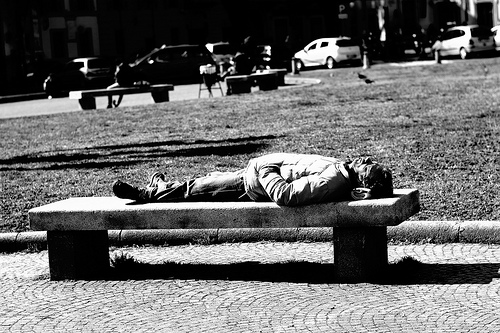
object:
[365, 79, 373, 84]
bird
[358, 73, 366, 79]
bird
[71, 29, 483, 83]
parking lot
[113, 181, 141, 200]
foot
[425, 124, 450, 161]
ground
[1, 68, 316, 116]
road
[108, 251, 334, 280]
weeds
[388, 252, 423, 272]
weeds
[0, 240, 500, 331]
concrete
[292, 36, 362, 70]
car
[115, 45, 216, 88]
car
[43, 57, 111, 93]
car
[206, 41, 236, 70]
car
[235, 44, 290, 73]
car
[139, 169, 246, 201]
jean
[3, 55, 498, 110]
street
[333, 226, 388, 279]
support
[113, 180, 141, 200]
shoes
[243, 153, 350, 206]
jacket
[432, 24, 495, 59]
car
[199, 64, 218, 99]
bin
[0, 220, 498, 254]
curb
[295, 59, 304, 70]
car tire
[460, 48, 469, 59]
tire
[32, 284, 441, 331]
brick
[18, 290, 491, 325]
pavement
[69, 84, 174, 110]
bench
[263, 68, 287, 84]
bench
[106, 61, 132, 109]
person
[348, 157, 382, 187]
head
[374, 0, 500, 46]
home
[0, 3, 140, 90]
building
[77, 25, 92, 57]
door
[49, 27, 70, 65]
door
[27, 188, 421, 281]
bench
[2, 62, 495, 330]
park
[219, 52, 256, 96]
person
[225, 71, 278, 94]
bench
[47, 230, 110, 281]
support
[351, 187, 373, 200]
cloth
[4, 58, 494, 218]
grass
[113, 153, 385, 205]
man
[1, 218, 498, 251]
curve